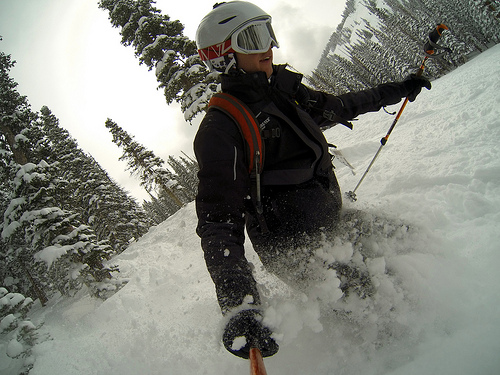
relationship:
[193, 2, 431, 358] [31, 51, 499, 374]
person in snow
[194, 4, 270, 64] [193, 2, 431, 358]
helmet worn on person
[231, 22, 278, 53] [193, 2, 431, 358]
goggles worn on person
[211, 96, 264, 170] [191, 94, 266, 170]
strap on shoulder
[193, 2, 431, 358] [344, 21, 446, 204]
person holding ski pole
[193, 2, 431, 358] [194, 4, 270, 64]
person wearing helmet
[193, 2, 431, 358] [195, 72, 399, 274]
person wearing jacket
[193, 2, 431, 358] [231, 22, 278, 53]
person wearing goggles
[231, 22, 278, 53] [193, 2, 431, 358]
goggles on person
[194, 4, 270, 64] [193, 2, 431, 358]
helmet on person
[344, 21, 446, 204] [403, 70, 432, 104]
ski pole in hand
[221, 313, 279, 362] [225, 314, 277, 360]
glove on hand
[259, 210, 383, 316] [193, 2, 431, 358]
snow in front of person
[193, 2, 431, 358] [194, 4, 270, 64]
person wears helmet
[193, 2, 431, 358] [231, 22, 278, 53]
person wears goggles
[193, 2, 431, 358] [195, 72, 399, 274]
person has jacket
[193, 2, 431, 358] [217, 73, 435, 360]
person has gloves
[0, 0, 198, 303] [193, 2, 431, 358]
trees behind person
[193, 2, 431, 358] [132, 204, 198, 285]
person make tracks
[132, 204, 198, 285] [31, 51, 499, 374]
tracks in snow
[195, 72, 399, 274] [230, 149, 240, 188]
jacket has stripes